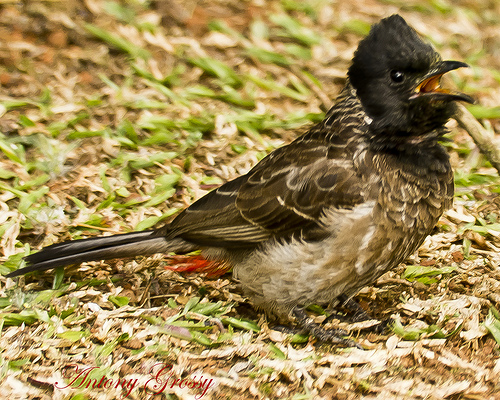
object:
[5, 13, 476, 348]
bird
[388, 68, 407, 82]
eye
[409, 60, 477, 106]
beak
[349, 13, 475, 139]
head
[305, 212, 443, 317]
stomach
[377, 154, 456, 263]
chest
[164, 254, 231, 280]
feathers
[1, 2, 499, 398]
grass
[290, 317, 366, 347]
feet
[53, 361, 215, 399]
name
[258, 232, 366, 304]
feathers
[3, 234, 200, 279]
feather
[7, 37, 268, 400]
leaves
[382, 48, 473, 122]
face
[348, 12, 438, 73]
hair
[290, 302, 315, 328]
leg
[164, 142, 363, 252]
right wing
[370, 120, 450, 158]
throat